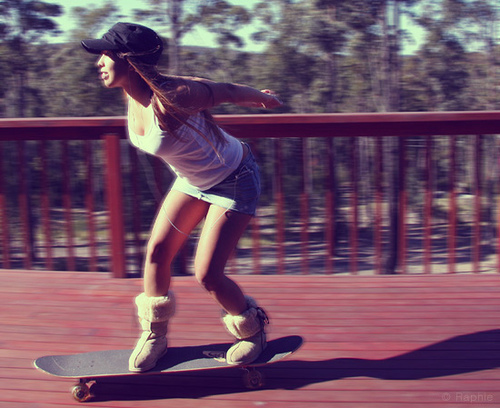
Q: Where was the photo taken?
A: It was taken at the porch.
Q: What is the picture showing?
A: It is showing a porch.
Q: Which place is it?
A: It is a porch.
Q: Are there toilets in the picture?
A: No, there are no toilets.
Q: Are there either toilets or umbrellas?
A: No, there are no toilets or umbrellas.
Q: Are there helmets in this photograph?
A: No, there are no helmets.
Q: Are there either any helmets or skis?
A: No, there are no helmets or skis.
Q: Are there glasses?
A: No, there are no glasses.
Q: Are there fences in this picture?
A: Yes, there is a fence.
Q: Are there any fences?
A: Yes, there is a fence.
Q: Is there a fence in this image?
A: Yes, there is a fence.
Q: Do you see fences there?
A: Yes, there is a fence.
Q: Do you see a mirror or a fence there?
A: Yes, there is a fence.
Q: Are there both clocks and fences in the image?
A: No, there is a fence but no clocks.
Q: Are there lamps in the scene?
A: No, there are no lamps.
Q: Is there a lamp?
A: No, there are no lamps.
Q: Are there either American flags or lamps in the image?
A: No, there are no lamps or American flags.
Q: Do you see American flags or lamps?
A: No, there are no lamps or American flags.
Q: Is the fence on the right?
A: Yes, the fence is on the right of the image.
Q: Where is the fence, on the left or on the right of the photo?
A: The fence is on the right of the image.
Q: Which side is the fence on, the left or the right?
A: The fence is on the right of the image.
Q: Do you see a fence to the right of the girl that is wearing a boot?
A: Yes, there is a fence to the right of the girl.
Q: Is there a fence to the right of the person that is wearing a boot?
A: Yes, there is a fence to the right of the girl.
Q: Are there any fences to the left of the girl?
A: No, the fence is to the right of the girl.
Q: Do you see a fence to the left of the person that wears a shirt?
A: No, the fence is to the right of the girl.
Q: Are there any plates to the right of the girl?
A: No, there is a fence to the right of the girl.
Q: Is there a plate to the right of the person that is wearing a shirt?
A: No, there is a fence to the right of the girl.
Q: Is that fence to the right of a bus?
A: No, the fence is to the right of a girl.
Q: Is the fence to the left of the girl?
A: No, the fence is to the right of the girl.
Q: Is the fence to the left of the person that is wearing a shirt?
A: No, the fence is to the right of the girl.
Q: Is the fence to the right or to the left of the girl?
A: The fence is to the right of the girl.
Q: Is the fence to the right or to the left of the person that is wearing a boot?
A: The fence is to the right of the girl.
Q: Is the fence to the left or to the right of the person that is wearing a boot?
A: The fence is to the right of the girl.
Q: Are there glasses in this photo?
A: No, there are no glasses.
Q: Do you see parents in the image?
A: No, there are no parents.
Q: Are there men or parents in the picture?
A: No, there are no parents or men.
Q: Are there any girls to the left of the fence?
A: Yes, there is a girl to the left of the fence.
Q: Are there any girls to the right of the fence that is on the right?
A: No, the girl is to the left of the fence.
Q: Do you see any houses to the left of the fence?
A: No, there is a girl to the left of the fence.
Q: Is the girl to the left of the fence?
A: Yes, the girl is to the left of the fence.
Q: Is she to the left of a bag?
A: No, the girl is to the left of the fence.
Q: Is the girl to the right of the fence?
A: No, the girl is to the left of the fence.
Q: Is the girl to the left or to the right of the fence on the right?
A: The girl is to the left of the fence.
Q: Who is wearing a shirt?
A: The girl is wearing a shirt.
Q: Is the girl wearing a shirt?
A: Yes, the girl is wearing a shirt.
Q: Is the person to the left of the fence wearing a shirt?
A: Yes, the girl is wearing a shirt.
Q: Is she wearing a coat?
A: No, the girl is wearing a shirt.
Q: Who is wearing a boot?
A: The girl is wearing a boot.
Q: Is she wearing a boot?
A: Yes, the girl is wearing a boot.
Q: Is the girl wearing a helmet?
A: No, the girl is wearing a boot.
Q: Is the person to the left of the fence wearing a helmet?
A: No, the girl is wearing a boot.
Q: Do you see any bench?
A: No, there are no benches.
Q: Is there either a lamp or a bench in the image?
A: No, there are no benches or lamps.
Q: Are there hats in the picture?
A: Yes, there is a hat.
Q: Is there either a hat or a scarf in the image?
A: Yes, there is a hat.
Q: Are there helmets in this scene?
A: No, there are no helmets.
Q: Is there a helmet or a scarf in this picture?
A: No, there are no helmets or scarves.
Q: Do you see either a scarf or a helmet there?
A: No, there are no helmets or scarves.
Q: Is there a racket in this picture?
A: No, there are no rackets.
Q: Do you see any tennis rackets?
A: No, there are no tennis rackets.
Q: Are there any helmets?
A: No, there are no helmets.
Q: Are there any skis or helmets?
A: No, there are no helmets or skis.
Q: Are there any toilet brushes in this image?
A: No, there are no toilet brushes.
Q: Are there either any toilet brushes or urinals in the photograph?
A: No, there are no toilet brushes or urinals.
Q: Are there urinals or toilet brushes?
A: No, there are no toilet brushes or urinals.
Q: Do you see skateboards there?
A: Yes, there is a skateboard.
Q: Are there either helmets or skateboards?
A: Yes, there is a skateboard.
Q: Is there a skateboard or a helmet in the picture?
A: Yes, there is a skateboard.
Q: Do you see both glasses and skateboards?
A: No, there is a skateboard but no glasses.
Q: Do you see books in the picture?
A: No, there are no books.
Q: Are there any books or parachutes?
A: No, there are no books or parachutes.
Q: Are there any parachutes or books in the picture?
A: No, there are no books or parachutes.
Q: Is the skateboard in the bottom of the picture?
A: Yes, the skateboard is in the bottom of the image.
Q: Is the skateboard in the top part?
A: No, the skateboard is in the bottom of the image.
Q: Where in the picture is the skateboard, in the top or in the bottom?
A: The skateboard is in the bottom of the image.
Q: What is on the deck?
A: The skateboard is on the deck.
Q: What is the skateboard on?
A: The skateboard is on the deck.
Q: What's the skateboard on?
A: The skateboard is on the deck.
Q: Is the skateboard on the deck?
A: Yes, the skateboard is on the deck.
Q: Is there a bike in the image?
A: No, there are no bikes.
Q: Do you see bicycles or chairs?
A: No, there are no bicycles or chairs.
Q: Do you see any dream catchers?
A: No, there are no dream catchers.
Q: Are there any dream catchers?
A: No, there are no dream catchers.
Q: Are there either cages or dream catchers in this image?
A: No, there are no dream catchers or cages.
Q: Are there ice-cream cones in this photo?
A: No, there are no ice-cream cones.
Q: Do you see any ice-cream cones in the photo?
A: No, there are no ice-cream cones.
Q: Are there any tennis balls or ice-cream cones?
A: No, there are no ice-cream cones or tennis balls.